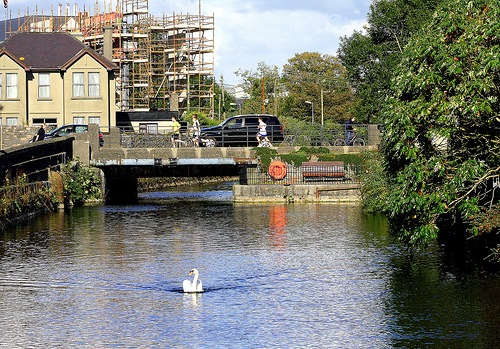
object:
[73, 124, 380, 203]
bridge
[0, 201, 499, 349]
water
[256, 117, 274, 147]
person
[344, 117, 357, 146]
person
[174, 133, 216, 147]
bicycle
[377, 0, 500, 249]
trees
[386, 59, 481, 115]
leaves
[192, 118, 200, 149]
people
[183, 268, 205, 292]
swan